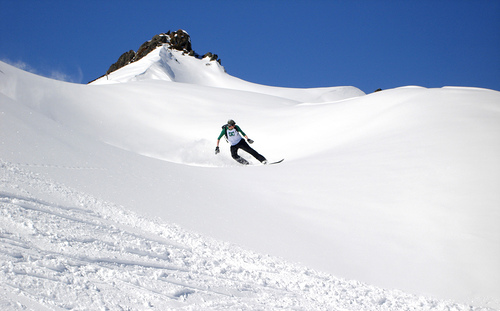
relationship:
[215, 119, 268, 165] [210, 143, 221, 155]
man wearing gloves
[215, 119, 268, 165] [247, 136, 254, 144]
man wearing gloves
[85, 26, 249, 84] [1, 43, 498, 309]
hill with snow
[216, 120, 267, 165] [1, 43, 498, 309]
man on snow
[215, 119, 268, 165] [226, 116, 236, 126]
man wearing hat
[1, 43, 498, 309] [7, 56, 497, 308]
snow on ground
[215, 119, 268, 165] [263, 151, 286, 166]
man on snowboard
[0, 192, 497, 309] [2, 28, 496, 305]
snow on ground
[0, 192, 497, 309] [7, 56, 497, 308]
snow on ground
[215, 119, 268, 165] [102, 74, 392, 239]
man on snow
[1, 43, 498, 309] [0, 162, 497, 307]
snow on ground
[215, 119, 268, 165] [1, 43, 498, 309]
man in snow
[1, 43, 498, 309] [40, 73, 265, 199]
snow on landscape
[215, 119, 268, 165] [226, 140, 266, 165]
man wears pants